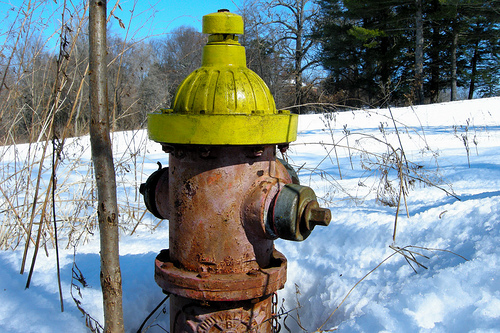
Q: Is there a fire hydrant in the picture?
A: Yes, there is a fire hydrant.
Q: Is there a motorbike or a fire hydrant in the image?
A: Yes, there is a fire hydrant.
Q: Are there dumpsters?
A: No, there are no dumpsters.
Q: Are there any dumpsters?
A: No, there are no dumpsters.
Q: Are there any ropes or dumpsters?
A: No, there are no dumpsters or ropes.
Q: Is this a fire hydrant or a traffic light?
A: This is a fire hydrant.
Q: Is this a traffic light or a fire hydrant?
A: This is a fire hydrant.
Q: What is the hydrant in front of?
A: The hydrant is in front of the tree.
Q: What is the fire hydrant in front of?
A: The hydrant is in front of the tree.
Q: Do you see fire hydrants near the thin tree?
A: Yes, there is a fire hydrant near the tree.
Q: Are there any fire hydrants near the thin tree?
A: Yes, there is a fire hydrant near the tree.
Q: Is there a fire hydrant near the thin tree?
A: Yes, there is a fire hydrant near the tree.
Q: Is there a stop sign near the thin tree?
A: No, there is a fire hydrant near the tree.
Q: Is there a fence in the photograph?
A: No, there are no fences.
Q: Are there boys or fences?
A: No, there are no fences or boys.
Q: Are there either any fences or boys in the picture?
A: No, there are no fences or boys.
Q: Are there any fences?
A: No, there are no fences.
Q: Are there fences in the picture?
A: No, there are no fences.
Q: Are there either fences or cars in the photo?
A: No, there are no fences or cars.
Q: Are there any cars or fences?
A: No, there are no fences or cars.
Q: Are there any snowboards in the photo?
A: No, there are no snowboards.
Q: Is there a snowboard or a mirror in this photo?
A: No, there are no snowboards or mirrors.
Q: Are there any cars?
A: No, there are no cars.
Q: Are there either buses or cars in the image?
A: No, there are no cars or buses.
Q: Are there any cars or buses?
A: No, there are no cars or buses.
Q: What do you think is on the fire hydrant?
A: The word is on the fire hydrant.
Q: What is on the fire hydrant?
A: The word is on the fire hydrant.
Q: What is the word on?
A: The word is on the fire hydrant.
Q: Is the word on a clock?
A: No, the word is on the hydrant.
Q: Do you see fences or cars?
A: No, there are no cars or fences.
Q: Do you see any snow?
A: Yes, there is snow.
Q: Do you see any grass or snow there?
A: Yes, there is snow.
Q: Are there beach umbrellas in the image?
A: No, there are no beach umbrellas.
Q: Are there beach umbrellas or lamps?
A: No, there are no beach umbrellas or lamps.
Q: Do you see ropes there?
A: No, there are no ropes.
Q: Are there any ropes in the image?
A: No, there are no ropes.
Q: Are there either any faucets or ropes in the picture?
A: No, there are no ropes or faucets.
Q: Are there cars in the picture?
A: No, there are no cars.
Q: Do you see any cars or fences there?
A: No, there are no cars or fences.